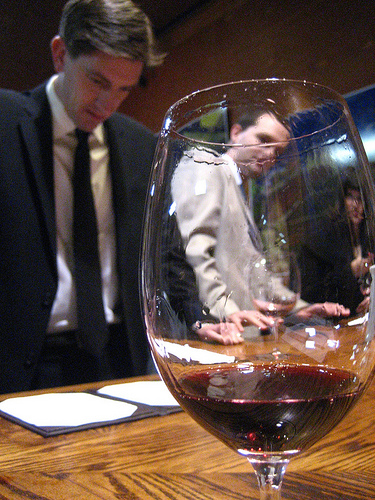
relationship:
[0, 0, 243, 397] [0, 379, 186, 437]
man examining menu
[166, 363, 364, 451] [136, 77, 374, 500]
liquid inside of glass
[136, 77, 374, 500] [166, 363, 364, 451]
glass with liquid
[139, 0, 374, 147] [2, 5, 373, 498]
wall connects building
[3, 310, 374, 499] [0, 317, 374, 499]
wood finish is mixed with wood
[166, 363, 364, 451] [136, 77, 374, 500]
liquid in glass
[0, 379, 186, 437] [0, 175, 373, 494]
menu on table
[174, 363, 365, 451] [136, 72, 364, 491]
liquid in glass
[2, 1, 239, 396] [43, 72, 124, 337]
man wearing shirt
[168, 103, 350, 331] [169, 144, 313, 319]
man wearing jacket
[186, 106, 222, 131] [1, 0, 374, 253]
image on wall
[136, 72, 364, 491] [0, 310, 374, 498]
glass on table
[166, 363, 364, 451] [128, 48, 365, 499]
liquid in glass